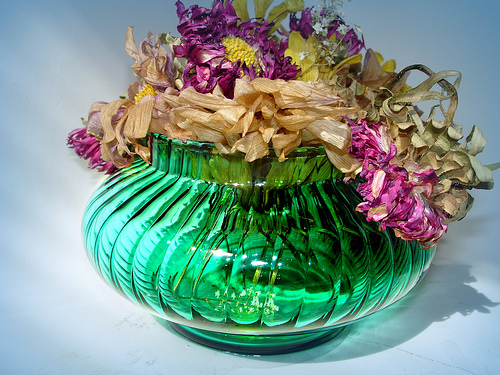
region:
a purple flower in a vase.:
[336, 108, 455, 248]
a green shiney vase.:
[74, 132, 434, 357]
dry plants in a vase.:
[376, 60, 490, 216]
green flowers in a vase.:
[211, 25, 280, 75]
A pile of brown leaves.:
[151, 70, 314, 159]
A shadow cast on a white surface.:
[404, 265, 483, 340]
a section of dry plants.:
[278, 35, 383, 109]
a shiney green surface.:
[192, 219, 331, 304]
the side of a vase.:
[126, 203, 207, 331]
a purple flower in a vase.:
[47, 105, 117, 199]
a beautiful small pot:
[50, 11, 499, 361]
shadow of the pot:
[408, 288, 498, 337]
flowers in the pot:
[146, 48, 485, 254]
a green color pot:
[101, 210, 364, 341]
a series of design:
[104, 188, 437, 318]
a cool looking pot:
[66, 123, 498, 360]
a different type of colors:
[73, 28, 499, 250]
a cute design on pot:
[81, 18, 498, 249]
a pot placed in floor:
[26, 9, 481, 358]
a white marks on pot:
[203, 243, 257, 267]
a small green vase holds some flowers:
[74, 8, 486, 348]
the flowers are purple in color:
[186, 8, 319, 83]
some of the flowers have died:
[132, 44, 306, 129]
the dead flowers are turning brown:
[128, 70, 312, 167]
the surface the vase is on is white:
[58, 197, 468, 359]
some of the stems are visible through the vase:
[165, 185, 355, 325]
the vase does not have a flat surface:
[132, 162, 367, 282]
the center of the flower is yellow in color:
[212, 21, 258, 73]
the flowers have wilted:
[303, 75, 475, 240]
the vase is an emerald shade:
[85, 125, 423, 329]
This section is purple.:
[381, 180, 409, 222]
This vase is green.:
[166, 265, 327, 306]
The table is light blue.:
[59, 287, 101, 359]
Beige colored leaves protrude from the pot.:
[186, 90, 317, 158]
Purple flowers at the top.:
[176, 5, 221, 73]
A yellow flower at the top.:
[286, 33, 332, 83]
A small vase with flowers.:
[49, 0, 473, 362]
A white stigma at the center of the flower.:
[298, 50, 310, 62]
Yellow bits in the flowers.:
[222, 33, 256, 67]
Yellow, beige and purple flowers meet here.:
[65, 78, 163, 174]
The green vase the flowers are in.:
[82, 137, 459, 352]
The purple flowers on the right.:
[348, 133, 443, 246]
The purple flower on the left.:
[71, 118, 118, 174]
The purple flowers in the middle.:
[174, 4, 359, 95]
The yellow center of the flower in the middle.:
[214, 34, 265, 70]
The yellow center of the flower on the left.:
[132, 84, 154, 101]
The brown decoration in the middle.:
[128, 85, 365, 168]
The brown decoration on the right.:
[376, 66, 490, 216]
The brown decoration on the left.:
[95, 93, 152, 163]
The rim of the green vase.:
[144, 134, 346, 176]